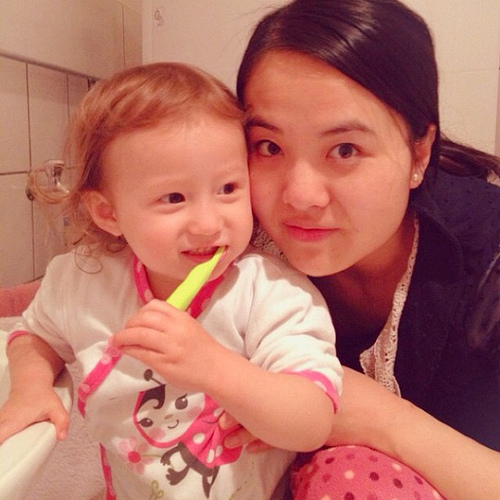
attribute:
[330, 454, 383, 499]
polka dot — pink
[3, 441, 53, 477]
bathtub — white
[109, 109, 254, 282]
face — happy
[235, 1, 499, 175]
hair — long, dark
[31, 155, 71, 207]
faucet — in background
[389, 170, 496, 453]
blazer — blue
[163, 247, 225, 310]
brush — yellow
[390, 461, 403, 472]
polka dots — pink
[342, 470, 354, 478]
polka dots — pink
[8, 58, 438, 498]
girl — small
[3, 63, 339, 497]
girl — little